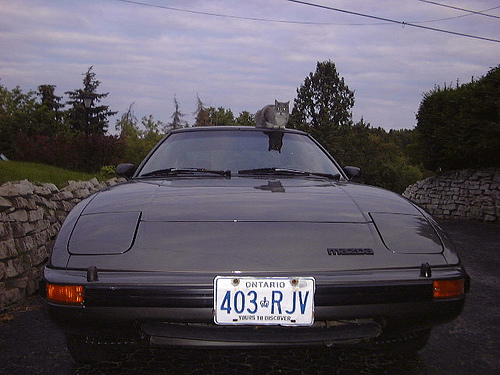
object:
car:
[35, 110, 474, 372]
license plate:
[208, 271, 319, 326]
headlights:
[23, 264, 101, 312]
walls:
[0, 177, 52, 258]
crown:
[284, 269, 312, 291]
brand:
[320, 233, 382, 262]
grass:
[15, 159, 77, 189]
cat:
[253, 96, 299, 134]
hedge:
[411, 63, 500, 175]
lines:
[389, 0, 500, 42]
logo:
[305, 215, 446, 288]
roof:
[164, 116, 312, 140]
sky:
[16, 0, 327, 77]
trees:
[59, 64, 120, 167]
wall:
[422, 172, 492, 220]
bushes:
[425, 90, 492, 138]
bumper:
[110, 268, 402, 351]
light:
[422, 268, 476, 304]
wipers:
[235, 161, 343, 180]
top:
[227, 122, 360, 188]